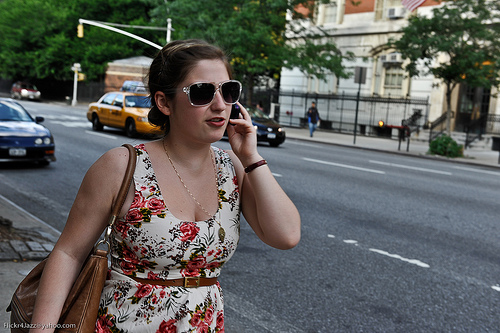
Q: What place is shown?
A: It is a street.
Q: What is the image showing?
A: It is showing a street.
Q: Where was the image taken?
A: It was taken at the street.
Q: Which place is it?
A: It is a street.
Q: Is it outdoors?
A: Yes, it is outdoors.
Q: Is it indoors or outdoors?
A: It is outdoors.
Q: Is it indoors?
A: No, it is outdoors.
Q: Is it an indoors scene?
A: No, it is outdoors.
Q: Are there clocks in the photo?
A: No, there are no clocks.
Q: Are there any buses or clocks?
A: No, there are no clocks or buses.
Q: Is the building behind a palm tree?
A: No, the building is behind the fence.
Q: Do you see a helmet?
A: No, there are no helmets.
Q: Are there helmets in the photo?
A: No, there are no helmets.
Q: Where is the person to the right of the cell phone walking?
A: The person is walking on the sidewalk.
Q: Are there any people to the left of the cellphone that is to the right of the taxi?
A: No, the person is to the right of the cellphone.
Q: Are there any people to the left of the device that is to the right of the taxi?
A: No, the person is to the right of the cellphone.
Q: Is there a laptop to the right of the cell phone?
A: No, there is a person to the right of the cell phone.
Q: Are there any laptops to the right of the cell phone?
A: No, there is a person to the right of the cell phone.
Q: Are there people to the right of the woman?
A: Yes, there is a person to the right of the woman.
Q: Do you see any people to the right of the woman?
A: Yes, there is a person to the right of the woman.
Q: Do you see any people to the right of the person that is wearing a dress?
A: Yes, there is a person to the right of the woman.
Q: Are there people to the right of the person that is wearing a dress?
A: Yes, there is a person to the right of the woman.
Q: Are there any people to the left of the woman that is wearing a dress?
A: No, the person is to the right of the woman.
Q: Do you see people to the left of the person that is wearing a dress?
A: No, the person is to the right of the woman.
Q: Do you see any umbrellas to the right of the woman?
A: No, there is a person to the right of the woman.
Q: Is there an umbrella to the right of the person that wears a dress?
A: No, there is a person to the right of the woman.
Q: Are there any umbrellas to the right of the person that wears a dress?
A: No, there is a person to the right of the woman.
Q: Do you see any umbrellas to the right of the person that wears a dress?
A: No, there is a person to the right of the woman.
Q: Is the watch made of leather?
A: Yes, the watch is made of leather.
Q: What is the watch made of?
A: The watch is made of leather.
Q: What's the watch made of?
A: The watch is made of leather.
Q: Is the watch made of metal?
A: No, the watch is made of leather.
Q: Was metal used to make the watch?
A: No, the watch is made of leather.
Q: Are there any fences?
A: Yes, there is a fence.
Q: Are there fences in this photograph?
A: Yes, there is a fence.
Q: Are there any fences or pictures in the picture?
A: Yes, there is a fence.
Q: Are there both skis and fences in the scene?
A: No, there is a fence but no skis.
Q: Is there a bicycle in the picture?
A: No, there are no bicycles.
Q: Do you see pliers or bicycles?
A: No, there are no bicycles or pliers.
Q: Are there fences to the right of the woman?
A: Yes, there is a fence to the right of the woman.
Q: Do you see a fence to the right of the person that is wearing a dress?
A: Yes, there is a fence to the right of the woman.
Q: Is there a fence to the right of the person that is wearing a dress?
A: Yes, there is a fence to the right of the woman.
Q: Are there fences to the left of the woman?
A: No, the fence is to the right of the woman.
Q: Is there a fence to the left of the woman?
A: No, the fence is to the right of the woman.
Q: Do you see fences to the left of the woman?
A: No, the fence is to the right of the woman.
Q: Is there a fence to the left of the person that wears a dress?
A: No, the fence is to the right of the woman.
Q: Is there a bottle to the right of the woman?
A: No, there is a fence to the right of the woman.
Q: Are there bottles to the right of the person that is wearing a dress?
A: No, there is a fence to the right of the woman.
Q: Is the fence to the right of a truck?
A: No, the fence is to the right of the woman.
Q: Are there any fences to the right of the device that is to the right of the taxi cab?
A: Yes, there is a fence to the right of the cellphone.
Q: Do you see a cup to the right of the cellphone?
A: No, there is a fence to the right of the cellphone.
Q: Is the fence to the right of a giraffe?
A: No, the fence is to the right of the mobile phone.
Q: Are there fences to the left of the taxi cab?
A: No, the fence is to the right of the taxi cab.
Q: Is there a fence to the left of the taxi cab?
A: No, the fence is to the right of the taxi cab.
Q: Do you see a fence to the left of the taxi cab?
A: No, the fence is to the right of the taxi cab.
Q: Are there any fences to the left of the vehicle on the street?
A: No, the fence is to the right of the taxi cab.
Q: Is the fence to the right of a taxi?
A: Yes, the fence is to the right of a taxi.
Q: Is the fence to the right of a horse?
A: No, the fence is to the right of a taxi.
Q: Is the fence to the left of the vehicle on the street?
A: No, the fence is to the right of the taxi cab.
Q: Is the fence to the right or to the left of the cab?
A: The fence is to the right of the cab.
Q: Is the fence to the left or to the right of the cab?
A: The fence is to the right of the cab.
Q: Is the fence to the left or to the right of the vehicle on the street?
A: The fence is to the right of the cab.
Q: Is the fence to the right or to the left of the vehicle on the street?
A: The fence is to the right of the cab.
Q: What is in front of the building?
A: The fence is in front of the building.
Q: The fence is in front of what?
A: The fence is in front of the building.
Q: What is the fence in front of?
A: The fence is in front of the building.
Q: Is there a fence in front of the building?
A: Yes, there is a fence in front of the building.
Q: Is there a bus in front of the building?
A: No, there is a fence in front of the building.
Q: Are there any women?
A: Yes, there is a woman.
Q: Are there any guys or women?
A: Yes, there is a woman.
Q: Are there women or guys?
A: Yes, there is a woman.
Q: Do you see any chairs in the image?
A: No, there are no chairs.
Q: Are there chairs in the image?
A: No, there are no chairs.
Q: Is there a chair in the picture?
A: No, there are no chairs.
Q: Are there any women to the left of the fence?
A: Yes, there is a woman to the left of the fence.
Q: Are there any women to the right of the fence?
A: No, the woman is to the left of the fence.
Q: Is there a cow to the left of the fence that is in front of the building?
A: No, there is a woman to the left of the fence.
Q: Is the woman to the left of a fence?
A: Yes, the woman is to the left of a fence.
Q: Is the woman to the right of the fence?
A: No, the woman is to the left of the fence.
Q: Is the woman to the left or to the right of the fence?
A: The woman is to the left of the fence.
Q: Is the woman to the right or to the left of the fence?
A: The woman is to the left of the fence.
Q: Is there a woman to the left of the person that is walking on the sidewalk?
A: Yes, there is a woman to the left of the person.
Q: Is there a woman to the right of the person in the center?
A: No, the woman is to the left of the person.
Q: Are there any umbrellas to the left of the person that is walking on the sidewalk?
A: No, there is a woman to the left of the person.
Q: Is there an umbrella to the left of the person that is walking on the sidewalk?
A: No, there is a woman to the left of the person.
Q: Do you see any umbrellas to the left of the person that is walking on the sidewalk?
A: No, there is a woman to the left of the person.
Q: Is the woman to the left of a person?
A: Yes, the woman is to the left of a person.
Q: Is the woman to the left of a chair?
A: No, the woman is to the left of a person.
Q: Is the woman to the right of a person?
A: No, the woman is to the left of a person.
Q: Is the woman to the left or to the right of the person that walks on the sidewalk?
A: The woman is to the left of the person.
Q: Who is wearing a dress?
A: The woman is wearing a dress.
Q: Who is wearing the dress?
A: The woman is wearing a dress.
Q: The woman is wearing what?
A: The woman is wearing a dress.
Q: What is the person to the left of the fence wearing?
A: The woman is wearing a dress.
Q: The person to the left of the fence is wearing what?
A: The woman is wearing a dress.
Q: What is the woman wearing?
A: The woman is wearing a dress.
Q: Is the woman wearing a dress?
A: Yes, the woman is wearing a dress.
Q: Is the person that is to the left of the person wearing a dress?
A: Yes, the woman is wearing a dress.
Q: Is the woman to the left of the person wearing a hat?
A: No, the woman is wearing a dress.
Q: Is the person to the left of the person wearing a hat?
A: No, the woman is wearing a dress.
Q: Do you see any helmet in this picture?
A: No, there are no helmets.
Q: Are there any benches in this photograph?
A: No, there are no benches.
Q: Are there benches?
A: No, there are no benches.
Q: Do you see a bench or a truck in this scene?
A: No, there are no benches or trucks.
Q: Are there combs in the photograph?
A: No, there are no combs.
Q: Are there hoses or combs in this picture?
A: No, there are no combs or hoses.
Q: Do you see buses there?
A: No, there are no buses.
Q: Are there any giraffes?
A: No, there are no giraffes.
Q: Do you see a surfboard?
A: No, there are no surfboards.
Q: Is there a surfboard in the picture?
A: No, there are no surfboards.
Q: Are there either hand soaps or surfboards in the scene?
A: No, there are no surfboards or hand soaps.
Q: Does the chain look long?
A: Yes, the chain is long.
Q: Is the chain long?
A: Yes, the chain is long.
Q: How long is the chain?
A: The chain is long.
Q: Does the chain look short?
A: No, the chain is long.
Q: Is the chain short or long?
A: The chain is long.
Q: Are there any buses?
A: No, there are no buses.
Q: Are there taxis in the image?
A: Yes, there is a taxi.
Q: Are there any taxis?
A: Yes, there is a taxi.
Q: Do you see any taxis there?
A: Yes, there is a taxi.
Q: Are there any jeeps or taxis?
A: Yes, there is a taxi.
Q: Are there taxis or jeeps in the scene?
A: Yes, there is a taxi.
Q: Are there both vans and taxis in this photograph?
A: No, there is a taxi but no vans.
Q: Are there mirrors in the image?
A: No, there are no mirrors.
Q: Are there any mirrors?
A: No, there are no mirrors.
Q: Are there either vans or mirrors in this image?
A: No, there are no mirrors or vans.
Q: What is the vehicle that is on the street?
A: The vehicle is a taxi.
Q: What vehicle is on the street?
A: The vehicle is a taxi.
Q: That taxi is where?
A: The taxi is on the street.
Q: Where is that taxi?
A: The taxi is on the street.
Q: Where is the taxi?
A: The taxi is on the street.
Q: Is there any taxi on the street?
A: Yes, there is a taxi on the street.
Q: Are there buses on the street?
A: No, there is a taxi on the street.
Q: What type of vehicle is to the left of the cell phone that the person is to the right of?
A: The vehicle is a taxi.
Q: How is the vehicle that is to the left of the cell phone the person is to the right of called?
A: The vehicle is a taxi.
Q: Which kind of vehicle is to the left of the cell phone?
A: The vehicle is a taxi.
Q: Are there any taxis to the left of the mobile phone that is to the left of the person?
A: Yes, there is a taxi to the left of the mobile phone.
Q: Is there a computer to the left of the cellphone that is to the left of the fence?
A: No, there is a taxi to the left of the mobile phone.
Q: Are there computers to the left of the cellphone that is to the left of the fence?
A: No, there is a taxi to the left of the mobile phone.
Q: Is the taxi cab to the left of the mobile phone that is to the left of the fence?
A: Yes, the taxi cab is to the left of the mobile phone.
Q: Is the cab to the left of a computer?
A: No, the cab is to the left of the mobile phone.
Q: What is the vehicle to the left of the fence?
A: The vehicle is a taxi.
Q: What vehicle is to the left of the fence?
A: The vehicle is a taxi.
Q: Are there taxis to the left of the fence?
A: Yes, there is a taxi to the left of the fence.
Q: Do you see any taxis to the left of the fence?
A: Yes, there is a taxi to the left of the fence.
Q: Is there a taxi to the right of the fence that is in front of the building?
A: No, the taxi is to the left of the fence.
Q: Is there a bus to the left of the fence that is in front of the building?
A: No, there is a taxi to the left of the fence.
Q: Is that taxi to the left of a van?
A: No, the taxi is to the left of the fence.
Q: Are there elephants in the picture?
A: No, there are no elephants.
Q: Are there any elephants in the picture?
A: No, there are no elephants.